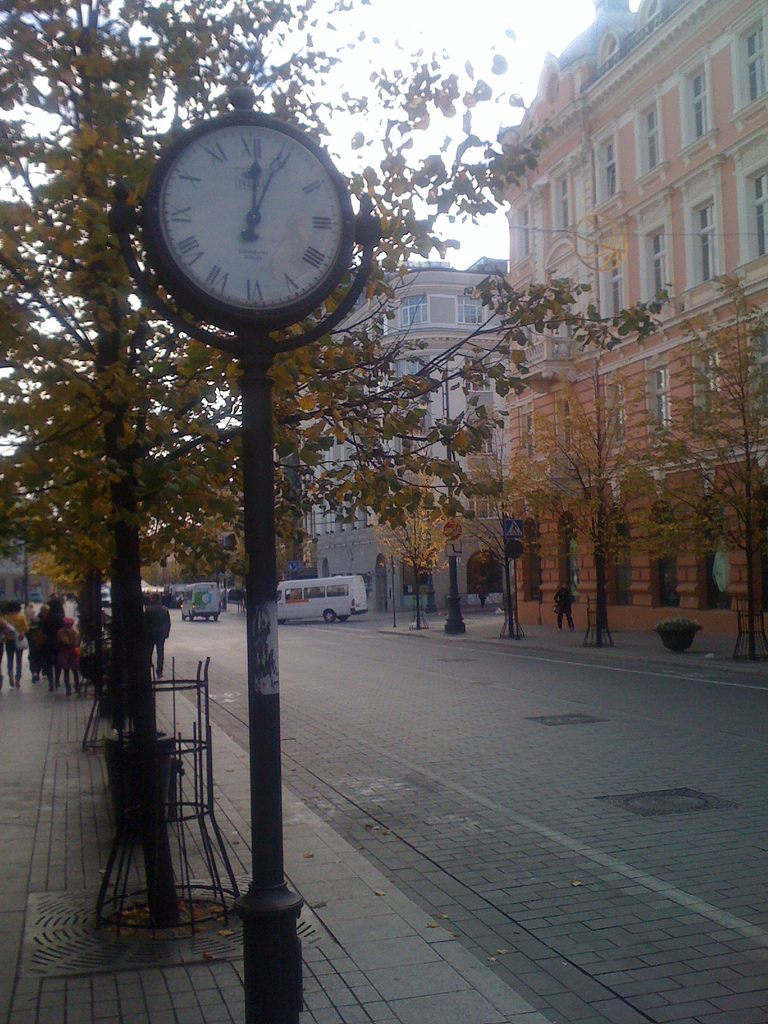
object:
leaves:
[464, 265, 674, 353]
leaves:
[67, 43, 163, 126]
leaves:
[71, 41, 150, 101]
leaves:
[152, 466, 226, 518]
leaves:
[369, 43, 492, 139]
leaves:
[323, 460, 423, 529]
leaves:
[39, 517, 115, 567]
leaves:
[151, 14, 221, 83]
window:
[683, 184, 726, 290]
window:
[637, 216, 674, 309]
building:
[496, 0, 768, 636]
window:
[678, 61, 713, 149]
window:
[594, 132, 622, 208]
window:
[551, 172, 578, 240]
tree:
[451, 394, 572, 637]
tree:
[0, 0, 675, 925]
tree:
[367, 429, 472, 632]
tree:
[614, 273, 768, 662]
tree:
[506, 304, 684, 647]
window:
[598, 221, 631, 327]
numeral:
[239, 137, 261, 159]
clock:
[143, 109, 354, 334]